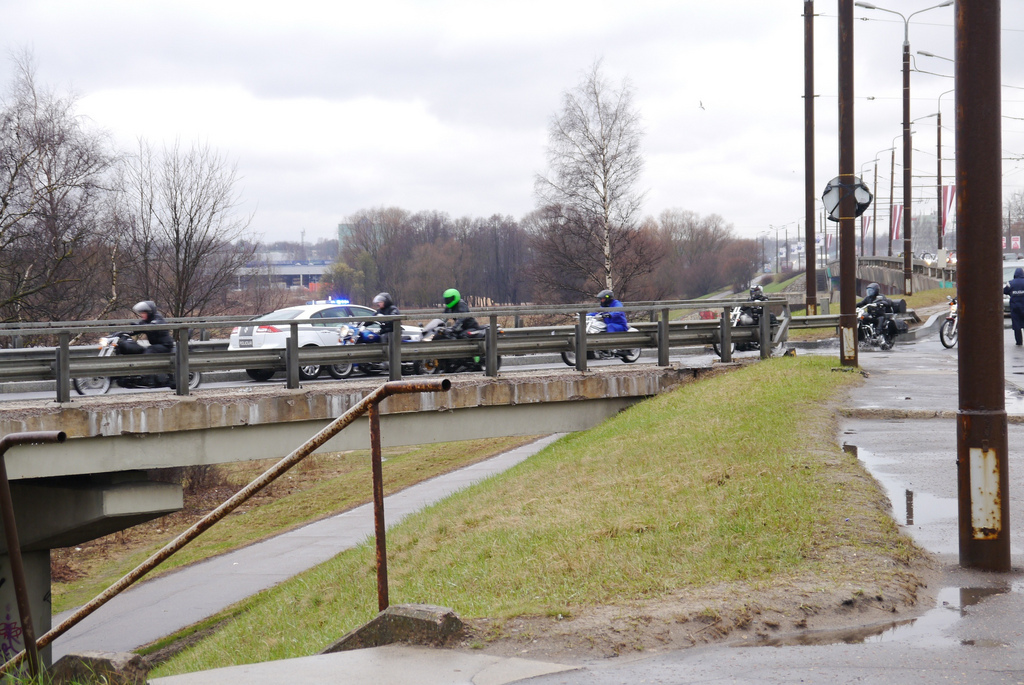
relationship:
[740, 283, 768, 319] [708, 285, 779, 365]
person on motorcycle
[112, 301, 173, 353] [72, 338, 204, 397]
man on motorcycle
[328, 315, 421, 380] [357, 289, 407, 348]
motorcycle on person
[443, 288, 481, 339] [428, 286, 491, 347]
motorcycle rider on motorcycle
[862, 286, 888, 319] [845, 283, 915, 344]
person on motorcycle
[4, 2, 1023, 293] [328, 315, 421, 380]
sky above motorcycle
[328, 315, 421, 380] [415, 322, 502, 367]
motorcycle above motorcycle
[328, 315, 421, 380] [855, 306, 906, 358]
motorcycle above motorcycle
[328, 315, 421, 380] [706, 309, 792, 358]
motorcycle above motorcycle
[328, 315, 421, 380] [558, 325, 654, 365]
motorcycle above motorcycle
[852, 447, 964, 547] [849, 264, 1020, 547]
puddle beside road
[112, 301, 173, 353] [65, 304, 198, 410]
man on motorcycle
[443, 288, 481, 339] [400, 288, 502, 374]
motorcycle rider on motorcycle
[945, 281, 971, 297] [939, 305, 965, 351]
person on motorcycle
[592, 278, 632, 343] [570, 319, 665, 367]
person on motorcycle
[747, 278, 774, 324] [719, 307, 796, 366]
person on motorcycle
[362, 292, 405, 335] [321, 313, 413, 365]
man on motorcycle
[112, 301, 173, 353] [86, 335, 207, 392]
man on motorcycle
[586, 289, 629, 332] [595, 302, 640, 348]
person wearing jacket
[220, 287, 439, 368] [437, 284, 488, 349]
car near motorcycle rider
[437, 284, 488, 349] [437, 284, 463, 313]
motorcycle rider wearing helmet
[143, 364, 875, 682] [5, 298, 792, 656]
grass growing near bridge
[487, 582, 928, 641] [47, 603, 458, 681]
mud formed near stairs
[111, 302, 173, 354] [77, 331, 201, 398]
man riding motorcycle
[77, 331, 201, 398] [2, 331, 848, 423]
motorcycle riding in street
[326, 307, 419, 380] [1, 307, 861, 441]
motorcycle riding in street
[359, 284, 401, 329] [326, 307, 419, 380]
man riding motorcycle